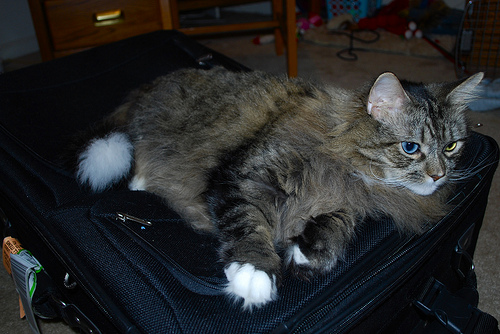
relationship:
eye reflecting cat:
[442, 136, 460, 153] [97, 57, 477, 284]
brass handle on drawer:
[94, 11, 125, 20] [40, 4, 168, 44]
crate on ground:
[330, 0, 379, 21] [0, 27, 500, 331]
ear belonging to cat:
[366, 71, 411, 121] [77, 68, 494, 314]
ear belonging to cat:
[437, 69, 485, 108] [77, 68, 494, 314]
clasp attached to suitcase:
[116, 206, 154, 228] [4, 37, 491, 329]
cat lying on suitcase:
[77, 68, 494, 314] [4, 37, 491, 329]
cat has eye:
[77, 68, 494, 314] [398, 135, 420, 157]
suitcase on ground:
[113, 240, 195, 325] [0, 14, 499, 331]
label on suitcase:
[2, 235, 42, 332] [4, 37, 491, 329]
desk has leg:
[132, 2, 350, 72] [285, 0, 298, 80]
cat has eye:
[174, 48, 489, 263] [394, 134, 422, 163]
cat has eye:
[174, 48, 489, 263] [437, 135, 459, 157]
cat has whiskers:
[77, 68, 494, 314] [356, 149, 487, 204]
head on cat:
[361, 70, 484, 200] [78, 38, 498, 309]